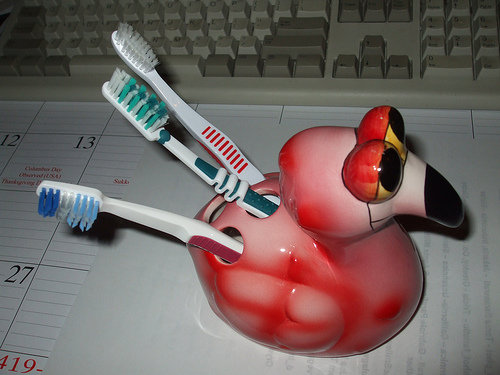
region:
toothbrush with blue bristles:
[28, 172, 243, 275]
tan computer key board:
[3, 3, 494, 118]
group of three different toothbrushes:
[30, 16, 282, 281]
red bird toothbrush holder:
[35, 16, 474, 360]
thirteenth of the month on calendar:
[8, 119, 104, 198]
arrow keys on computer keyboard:
[333, 29, 418, 100]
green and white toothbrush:
[97, 63, 277, 220]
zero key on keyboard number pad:
[418, 49, 478, 84]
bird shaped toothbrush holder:
[179, 103, 475, 363]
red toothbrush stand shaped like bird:
[175, 91, 482, 361]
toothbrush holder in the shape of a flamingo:
[187, 104, 463, 357]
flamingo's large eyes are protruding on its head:
[341, 103, 408, 201]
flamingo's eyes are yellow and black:
[373, 109, 408, 200]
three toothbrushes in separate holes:
[34, 18, 278, 265]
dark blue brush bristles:
[35, 185, 60, 218]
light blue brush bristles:
[66, 191, 98, 232]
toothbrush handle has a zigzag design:
[204, 168, 251, 206]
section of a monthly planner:
[0, 99, 142, 374]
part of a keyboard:
[1, 0, 498, 110]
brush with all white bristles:
[111, 23, 159, 76]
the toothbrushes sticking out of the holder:
[36, 21, 463, 358]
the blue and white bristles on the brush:
[34, 189, 100, 232]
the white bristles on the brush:
[113, 18, 156, 72]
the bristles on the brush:
[108, 65, 170, 131]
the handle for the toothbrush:
[103, 195, 241, 261]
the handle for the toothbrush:
[163, 131, 277, 218]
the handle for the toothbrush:
[150, 66, 263, 184]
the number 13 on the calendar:
[73, 133, 95, 149]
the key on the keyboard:
[359, 33, 386, 57]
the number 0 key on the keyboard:
[420, 51, 475, 83]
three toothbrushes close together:
[61, 48, 306, 297]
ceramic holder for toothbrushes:
[190, 150, 442, 350]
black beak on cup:
[396, 162, 458, 223]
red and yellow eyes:
[342, 103, 405, 194]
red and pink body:
[181, 243, 412, 348]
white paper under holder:
[84, 140, 219, 360]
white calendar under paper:
[1, 128, 169, 301]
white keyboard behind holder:
[4, 18, 487, 109]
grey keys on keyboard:
[212, 35, 429, 107]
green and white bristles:
[108, 72, 183, 144]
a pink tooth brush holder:
[2, 18, 492, 371]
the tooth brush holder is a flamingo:
[137, 101, 498, 364]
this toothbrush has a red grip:
[12, 162, 259, 298]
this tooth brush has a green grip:
[102, 70, 285, 245]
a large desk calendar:
[5, 95, 499, 372]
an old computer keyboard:
[1, 3, 498, 124]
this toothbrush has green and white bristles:
[93, 66, 198, 158]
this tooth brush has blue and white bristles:
[13, 164, 142, 263]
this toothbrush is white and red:
[96, 20, 292, 205]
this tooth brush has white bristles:
[99, 19, 194, 87]